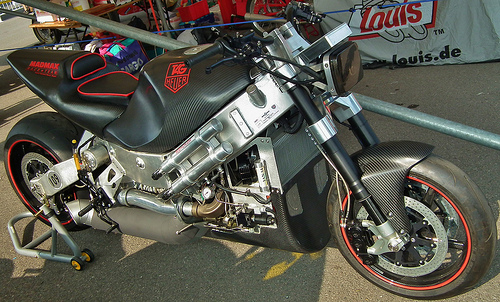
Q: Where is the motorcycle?
A: Sitting outside.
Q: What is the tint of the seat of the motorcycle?
A: Black and red.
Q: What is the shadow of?
A: A motorcycle.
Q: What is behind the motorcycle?
A: A slanted silver pole.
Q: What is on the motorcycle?
A: A wheel.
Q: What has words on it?
A: A cloth.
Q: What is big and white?
A: The cloth.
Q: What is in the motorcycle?
A: Text.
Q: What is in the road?
A: Tire.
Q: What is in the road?
A: Bike.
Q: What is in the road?
A: Motorcycle.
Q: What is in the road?
A: Motorcycle.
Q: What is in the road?
A: Bike.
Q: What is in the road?
A: Shadow.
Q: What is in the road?
A: Wheel.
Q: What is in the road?
A: Tire.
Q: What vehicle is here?
A: Motorcycle.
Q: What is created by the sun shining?
A: Shadows.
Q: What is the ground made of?
A: Concrete.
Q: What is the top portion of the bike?
A: Seat.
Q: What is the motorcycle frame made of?
A: Metal.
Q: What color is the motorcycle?
A: Black and silver.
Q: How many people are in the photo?
A: 0.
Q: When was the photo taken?
A: Daytime.